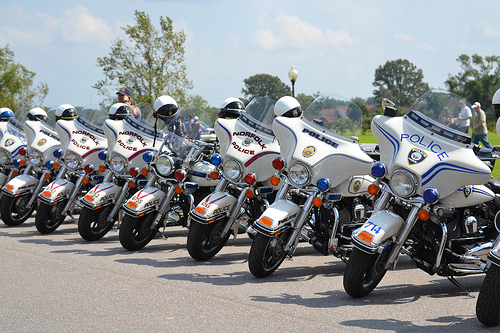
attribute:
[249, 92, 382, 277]
motorcycle — norfolks, several, white, parked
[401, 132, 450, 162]
writing — blue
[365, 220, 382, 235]
number — 714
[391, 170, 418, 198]
headlight — orange, off, blue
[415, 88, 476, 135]
shield — clear, small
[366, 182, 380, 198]
light — orange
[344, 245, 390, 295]
tire — rubber, black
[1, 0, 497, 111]
sky — blue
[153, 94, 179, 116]
helmet — placed, large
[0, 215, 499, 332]
road — grey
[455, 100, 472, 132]
man — walking, standing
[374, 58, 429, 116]
tree — tall, green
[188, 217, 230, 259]
wheel — black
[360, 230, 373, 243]
reflector — small